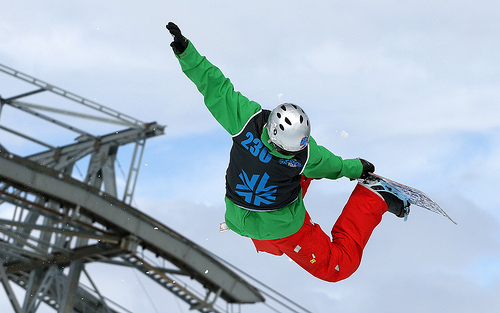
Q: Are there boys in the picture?
A: No, there are no boys.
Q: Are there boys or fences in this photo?
A: No, there are no boys or fences.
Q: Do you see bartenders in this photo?
A: No, there are no bartenders.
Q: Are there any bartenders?
A: No, there are no bartenders.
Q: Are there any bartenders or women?
A: No, there are no bartenders or women.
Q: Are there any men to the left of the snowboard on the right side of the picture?
A: Yes, there is a man to the left of the snowboard.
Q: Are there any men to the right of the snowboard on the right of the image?
A: No, the man is to the left of the snowboard.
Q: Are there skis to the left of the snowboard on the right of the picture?
A: No, there is a man to the left of the snowboard.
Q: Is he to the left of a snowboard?
A: Yes, the man is to the left of a snowboard.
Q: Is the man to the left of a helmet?
A: No, the man is to the left of a snowboard.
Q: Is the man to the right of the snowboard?
A: No, the man is to the left of the snowboard.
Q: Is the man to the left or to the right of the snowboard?
A: The man is to the left of the snowboard.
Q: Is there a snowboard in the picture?
A: Yes, there is a snowboard.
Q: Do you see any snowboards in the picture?
A: Yes, there is a snowboard.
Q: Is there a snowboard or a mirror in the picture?
A: Yes, there is a snowboard.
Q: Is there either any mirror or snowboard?
A: Yes, there is a snowboard.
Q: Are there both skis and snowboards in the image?
A: No, there is a snowboard but no skis.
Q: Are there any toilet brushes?
A: No, there are no toilet brushes.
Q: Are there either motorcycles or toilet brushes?
A: No, there are no toilet brushes or motorcycles.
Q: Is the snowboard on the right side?
A: Yes, the snowboard is on the right of the image.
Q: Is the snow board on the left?
A: No, the snow board is on the right of the image.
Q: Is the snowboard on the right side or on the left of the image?
A: The snowboard is on the right of the image.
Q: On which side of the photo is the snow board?
A: The snow board is on the right of the image.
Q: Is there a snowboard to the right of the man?
A: Yes, there is a snowboard to the right of the man.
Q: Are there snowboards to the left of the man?
A: No, the snowboard is to the right of the man.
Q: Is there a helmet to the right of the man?
A: No, there is a snowboard to the right of the man.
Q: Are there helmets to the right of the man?
A: No, there is a snowboard to the right of the man.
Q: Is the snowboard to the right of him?
A: Yes, the snowboard is to the right of the man.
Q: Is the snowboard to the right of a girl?
A: No, the snowboard is to the right of the man.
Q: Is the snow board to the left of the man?
A: No, the snow board is to the right of the man.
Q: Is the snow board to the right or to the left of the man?
A: The snow board is to the right of the man.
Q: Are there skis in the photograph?
A: No, there are no skis.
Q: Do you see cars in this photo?
A: No, there are no cars.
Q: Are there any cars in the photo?
A: No, there are no cars.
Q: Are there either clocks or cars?
A: No, there are no cars or clocks.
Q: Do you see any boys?
A: No, there are no boys.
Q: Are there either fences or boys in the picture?
A: No, there are no boys or fences.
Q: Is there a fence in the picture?
A: No, there are no fences.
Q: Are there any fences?
A: No, there are no fences.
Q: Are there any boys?
A: No, there are no boys.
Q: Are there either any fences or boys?
A: No, there are no boys or fences.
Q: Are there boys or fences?
A: No, there are no boys or fences.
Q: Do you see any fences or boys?
A: No, there are no boys or fences.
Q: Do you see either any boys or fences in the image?
A: No, there are no boys or fences.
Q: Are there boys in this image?
A: No, there are no boys.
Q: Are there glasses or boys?
A: No, there are no boys or glasses.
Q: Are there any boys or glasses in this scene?
A: No, there are no boys or glasses.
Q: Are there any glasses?
A: No, there are no glasses.